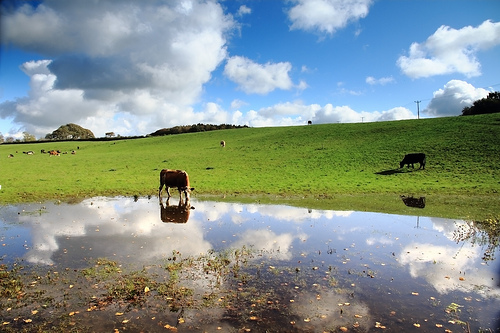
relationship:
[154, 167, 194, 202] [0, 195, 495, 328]
cow drinking from pond pond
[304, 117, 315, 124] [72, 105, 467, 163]
cow standing on hill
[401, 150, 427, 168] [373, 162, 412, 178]
cow has shadow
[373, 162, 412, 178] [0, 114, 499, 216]
shadow on grass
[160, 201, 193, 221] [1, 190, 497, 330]
reflection on puddle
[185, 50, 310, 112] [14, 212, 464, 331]
clouds reflected in pond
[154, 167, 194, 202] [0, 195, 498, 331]
cow drinking water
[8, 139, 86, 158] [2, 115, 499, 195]
cows in grass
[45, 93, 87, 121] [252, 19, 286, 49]
clouds in sky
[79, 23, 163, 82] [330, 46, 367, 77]
clouds in sky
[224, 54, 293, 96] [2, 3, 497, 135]
clouds in sky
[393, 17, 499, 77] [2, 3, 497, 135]
cloud in sky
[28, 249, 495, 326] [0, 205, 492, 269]
leaves in water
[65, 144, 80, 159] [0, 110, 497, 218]
cow in field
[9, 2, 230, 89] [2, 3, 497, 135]
clouds in sky